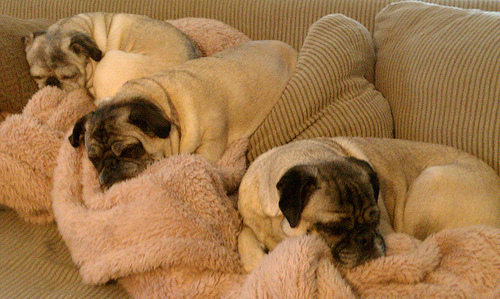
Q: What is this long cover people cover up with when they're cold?
A: Blanket.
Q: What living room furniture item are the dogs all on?
A: Couch.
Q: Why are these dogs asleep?
A: They're tired.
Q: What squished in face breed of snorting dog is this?
A: Pug.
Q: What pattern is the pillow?
A: Striped.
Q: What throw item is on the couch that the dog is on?
A: Pillow.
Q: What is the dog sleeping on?
A: A blanket.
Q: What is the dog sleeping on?
A: A blanket.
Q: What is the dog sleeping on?
A: A blanket.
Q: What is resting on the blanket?
A: A dog.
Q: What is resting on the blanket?
A: The dog.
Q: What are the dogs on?
A: A couch.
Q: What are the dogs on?
A: A blanket.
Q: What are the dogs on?
A: A blanket.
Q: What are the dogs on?
A: A blanket.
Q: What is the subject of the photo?
A: Animals.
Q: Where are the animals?
A: On pink blanket.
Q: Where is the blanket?
A: On couch.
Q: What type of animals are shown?
A: Dogs.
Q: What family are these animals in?
A: Canine.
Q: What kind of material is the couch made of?
A: Corduroy.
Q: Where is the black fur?
A: On dog's heads.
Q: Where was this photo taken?
A: In the living room.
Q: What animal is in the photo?
A: Dogs.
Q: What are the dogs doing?
A: Sleeping.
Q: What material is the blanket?
A: Fleece.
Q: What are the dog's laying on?
A: Couch.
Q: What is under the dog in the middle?
A: A pillow.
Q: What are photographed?
A: Dogs.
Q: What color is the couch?
A: Beige.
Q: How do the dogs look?
A: Sleepy.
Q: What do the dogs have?
A: A blanket.